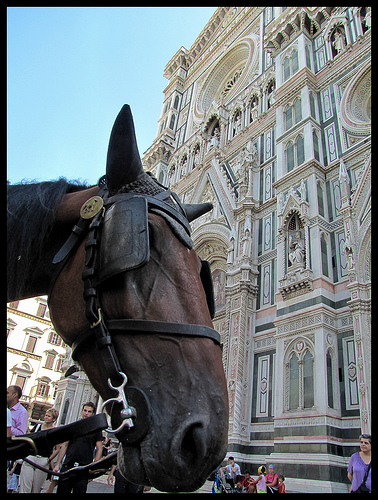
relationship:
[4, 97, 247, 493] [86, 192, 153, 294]
horse wearing blinders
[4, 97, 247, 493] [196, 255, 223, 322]
horse wearing blinders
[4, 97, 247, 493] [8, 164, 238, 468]
horse wearing harness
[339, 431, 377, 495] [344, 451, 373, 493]
woman wears top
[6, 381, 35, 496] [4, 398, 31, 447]
people wearing shirt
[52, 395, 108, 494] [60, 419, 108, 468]
people wearing shirt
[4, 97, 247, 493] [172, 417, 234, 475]
horse has nose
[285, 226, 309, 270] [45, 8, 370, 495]
statue on building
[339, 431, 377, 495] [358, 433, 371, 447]
woman has hair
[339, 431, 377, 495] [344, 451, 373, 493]
woman wearing top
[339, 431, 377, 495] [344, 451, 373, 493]
woman with top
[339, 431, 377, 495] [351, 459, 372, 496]
woman has bag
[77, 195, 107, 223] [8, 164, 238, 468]
piece of harness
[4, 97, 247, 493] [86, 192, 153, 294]
horse has blinders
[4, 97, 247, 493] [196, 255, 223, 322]
horse has blinders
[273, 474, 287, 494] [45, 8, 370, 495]
people front building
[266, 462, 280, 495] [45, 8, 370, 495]
people front building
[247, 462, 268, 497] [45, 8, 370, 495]
people front building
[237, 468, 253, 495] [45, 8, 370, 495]
people front building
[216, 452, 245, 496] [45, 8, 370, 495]
people front building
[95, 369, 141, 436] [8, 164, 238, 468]
clasp on harness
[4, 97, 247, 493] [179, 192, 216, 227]
horse has ear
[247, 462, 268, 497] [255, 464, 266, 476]
people with hat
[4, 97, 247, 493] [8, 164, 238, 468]
horse has harness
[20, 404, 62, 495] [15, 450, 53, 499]
people in pants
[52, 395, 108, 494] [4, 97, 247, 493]
people by horse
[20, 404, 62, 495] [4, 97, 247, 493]
people by horse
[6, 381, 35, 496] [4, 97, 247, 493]
people by horse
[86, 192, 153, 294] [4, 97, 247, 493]
blinders on horse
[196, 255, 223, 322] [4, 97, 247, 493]
blinders on horse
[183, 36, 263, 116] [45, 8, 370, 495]
window in building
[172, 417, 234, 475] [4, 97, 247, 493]
nose of horse